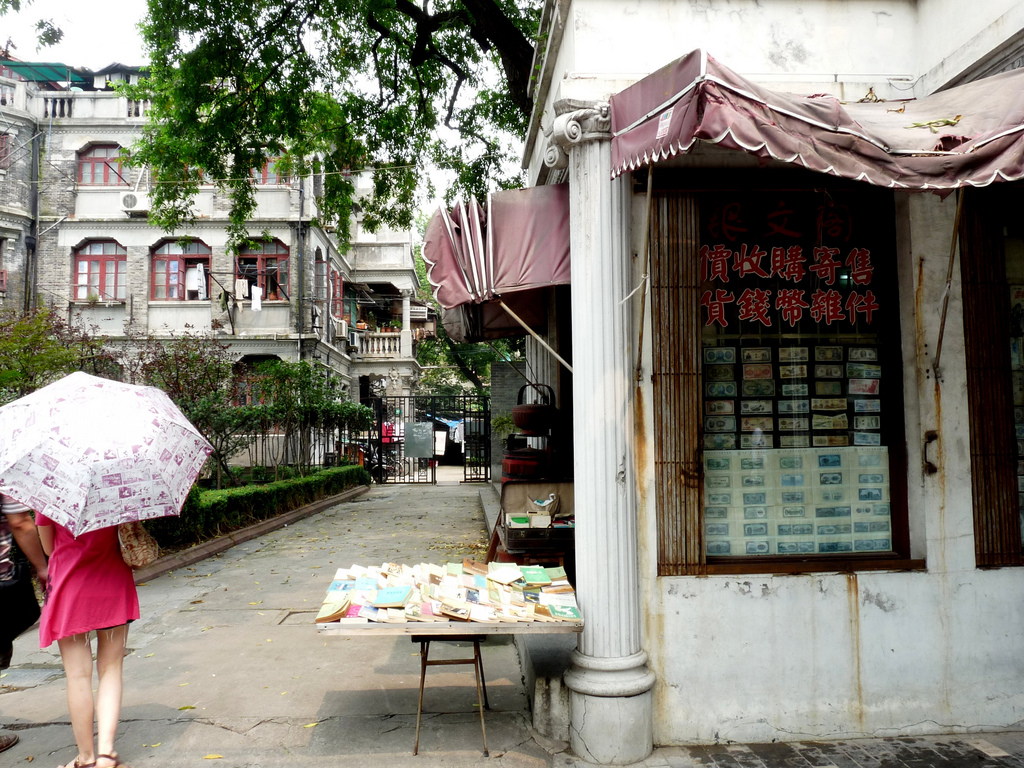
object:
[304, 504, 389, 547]
ground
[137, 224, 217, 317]
window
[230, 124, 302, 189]
window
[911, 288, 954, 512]
stain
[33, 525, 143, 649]
sundress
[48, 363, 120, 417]
top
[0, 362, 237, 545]
light umbrella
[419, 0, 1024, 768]
store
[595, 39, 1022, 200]
awning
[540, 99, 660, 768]
pillar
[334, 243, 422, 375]
balcony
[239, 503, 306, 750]
sidewalk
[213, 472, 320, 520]
hedge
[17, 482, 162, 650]
dress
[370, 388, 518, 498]
gate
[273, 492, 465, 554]
alleyway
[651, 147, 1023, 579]
windows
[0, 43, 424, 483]
building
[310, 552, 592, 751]
table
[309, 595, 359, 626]
books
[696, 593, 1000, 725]
wall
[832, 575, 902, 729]
rust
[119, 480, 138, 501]
pattern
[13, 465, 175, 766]
girl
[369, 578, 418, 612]
papers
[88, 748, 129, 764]
sandals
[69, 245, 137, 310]
window frames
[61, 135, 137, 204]
window frames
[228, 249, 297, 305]
window frames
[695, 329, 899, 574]
pictures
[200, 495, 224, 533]
hedges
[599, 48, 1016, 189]
window awning